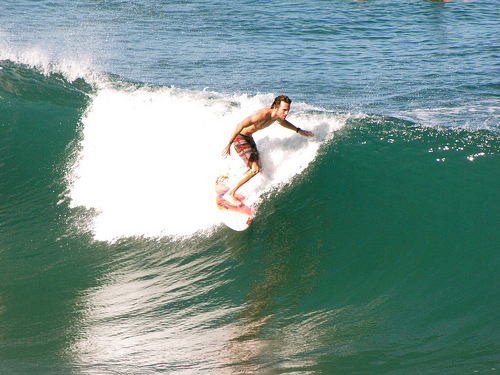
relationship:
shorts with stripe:
[226, 133, 267, 167] [227, 131, 256, 170]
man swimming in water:
[222, 95, 315, 207] [1, 1, 481, 369]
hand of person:
[292, 124, 316, 138] [210, 92, 322, 212]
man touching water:
[204, 86, 318, 207] [2, 48, 472, 348]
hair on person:
[260, 92, 299, 114] [206, 90, 336, 237]